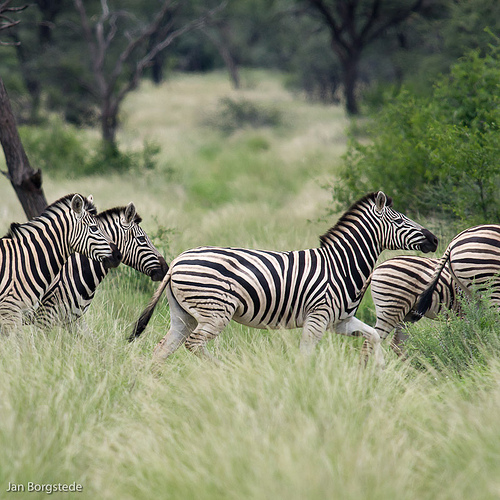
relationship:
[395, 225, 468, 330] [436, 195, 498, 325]
tail of zebra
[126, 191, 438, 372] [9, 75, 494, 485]
zebras walking on grass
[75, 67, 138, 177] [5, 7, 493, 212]
tree in background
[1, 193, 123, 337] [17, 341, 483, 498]
zebras on grass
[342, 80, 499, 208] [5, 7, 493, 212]
shrub in background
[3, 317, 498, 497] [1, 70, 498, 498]
grass on ground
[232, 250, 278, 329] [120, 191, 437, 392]
stripes on zebra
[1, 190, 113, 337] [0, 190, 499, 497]
zebras in grass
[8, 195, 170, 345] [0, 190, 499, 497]
zebras in grass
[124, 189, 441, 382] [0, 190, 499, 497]
zebras in grass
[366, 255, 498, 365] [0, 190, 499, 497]
zebras in grass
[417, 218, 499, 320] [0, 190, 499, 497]
zebras in grass